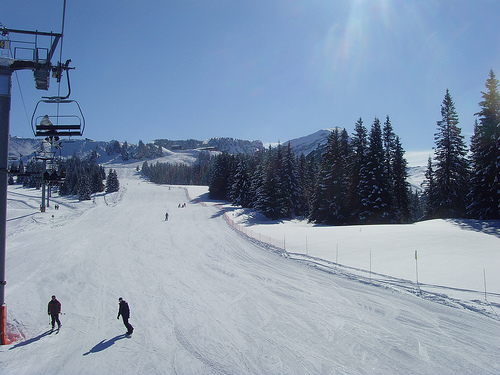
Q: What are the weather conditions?
A: It is clear.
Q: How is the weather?
A: It is clear.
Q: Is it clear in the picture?
A: Yes, it is clear.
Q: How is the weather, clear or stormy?
A: It is clear.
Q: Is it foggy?
A: No, it is clear.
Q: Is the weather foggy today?
A: No, it is clear.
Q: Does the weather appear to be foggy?
A: No, it is clear.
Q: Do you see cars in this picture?
A: No, there are no cars.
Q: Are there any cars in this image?
A: No, there are no cars.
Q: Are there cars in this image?
A: No, there are no cars.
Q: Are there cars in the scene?
A: No, there are no cars.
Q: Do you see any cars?
A: No, there are no cars.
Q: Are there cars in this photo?
A: No, there are no cars.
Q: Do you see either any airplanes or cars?
A: No, there are no cars or airplanes.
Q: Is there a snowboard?
A: No, there are no snowboards.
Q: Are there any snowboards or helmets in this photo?
A: No, there are no snowboards or helmets.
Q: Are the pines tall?
A: Yes, the pines are tall.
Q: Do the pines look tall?
A: Yes, the pines are tall.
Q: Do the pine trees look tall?
A: Yes, the pine trees are tall.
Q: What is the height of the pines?
A: The pines are tall.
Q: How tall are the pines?
A: The pines are tall.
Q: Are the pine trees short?
A: No, the pine trees are tall.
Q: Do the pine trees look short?
A: No, the pine trees are tall.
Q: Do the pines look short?
A: No, the pines are tall.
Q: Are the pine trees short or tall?
A: The pine trees are tall.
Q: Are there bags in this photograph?
A: No, there are no bags.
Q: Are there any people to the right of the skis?
A: Yes, there are people to the right of the skis.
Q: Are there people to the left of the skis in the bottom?
A: No, the people are to the right of the skis.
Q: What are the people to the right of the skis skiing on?
A: The people are skiing on the snow.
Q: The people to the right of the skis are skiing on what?
A: The people are skiing on the snow.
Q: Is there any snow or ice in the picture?
A: Yes, there is snow.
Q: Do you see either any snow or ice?
A: Yes, there is snow.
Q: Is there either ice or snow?
A: Yes, there is snow.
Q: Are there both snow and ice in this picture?
A: No, there is snow but no ice.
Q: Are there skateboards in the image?
A: No, there are no skateboards.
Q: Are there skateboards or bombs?
A: No, there are no skateboards or bombs.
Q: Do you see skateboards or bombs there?
A: No, there are no skateboards or bombs.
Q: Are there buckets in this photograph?
A: No, there are no buckets.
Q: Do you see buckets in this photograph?
A: No, there are no buckets.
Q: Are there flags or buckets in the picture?
A: No, there are no buckets or flags.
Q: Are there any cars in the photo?
A: No, there are no cars.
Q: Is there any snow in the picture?
A: Yes, there is snow.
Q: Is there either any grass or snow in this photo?
A: Yes, there is snow.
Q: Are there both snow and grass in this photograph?
A: No, there is snow but no grass.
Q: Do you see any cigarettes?
A: No, there are no cigarettes.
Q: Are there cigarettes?
A: No, there are no cigarettes.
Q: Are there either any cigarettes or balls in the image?
A: No, there are no cigarettes or balls.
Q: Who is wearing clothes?
A: The people are wearing clothes.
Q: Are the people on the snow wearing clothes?
A: Yes, the people are wearing clothes.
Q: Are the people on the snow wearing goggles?
A: No, the people are wearing clothes.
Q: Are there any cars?
A: No, there are no cars.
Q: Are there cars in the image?
A: No, there are no cars.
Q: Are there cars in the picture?
A: No, there are no cars.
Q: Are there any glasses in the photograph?
A: No, there are no glasses.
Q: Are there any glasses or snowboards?
A: No, there are no glasses or snowboards.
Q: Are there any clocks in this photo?
A: No, there are no clocks.